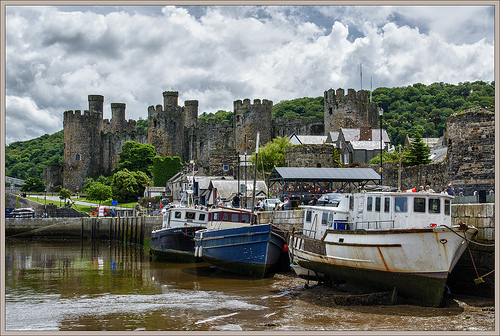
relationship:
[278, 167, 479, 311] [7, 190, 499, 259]
boat at dock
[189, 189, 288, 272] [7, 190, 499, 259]
boat at dock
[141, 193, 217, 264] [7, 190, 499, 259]
boat at dock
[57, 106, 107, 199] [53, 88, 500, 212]
tower of castle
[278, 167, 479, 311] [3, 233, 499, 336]
boat in water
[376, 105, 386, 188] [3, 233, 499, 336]
light near water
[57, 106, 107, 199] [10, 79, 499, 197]
tower on hill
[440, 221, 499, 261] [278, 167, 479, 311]
rope tying up boat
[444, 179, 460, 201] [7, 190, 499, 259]
onlooker on bridge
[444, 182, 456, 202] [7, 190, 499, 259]
onlooker on dock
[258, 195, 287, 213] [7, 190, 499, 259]
vehicle on dock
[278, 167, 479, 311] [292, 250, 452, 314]
boat has bottom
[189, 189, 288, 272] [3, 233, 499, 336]
boat in water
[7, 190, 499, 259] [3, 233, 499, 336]
dock over water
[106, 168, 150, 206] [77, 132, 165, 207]
foliage in foliage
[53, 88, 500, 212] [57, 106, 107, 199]
castle has tower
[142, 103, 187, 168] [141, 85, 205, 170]
tower in group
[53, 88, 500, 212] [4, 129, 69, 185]
castle near hillside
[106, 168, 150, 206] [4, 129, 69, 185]
foliage near hillside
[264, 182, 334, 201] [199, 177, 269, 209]
flag on building